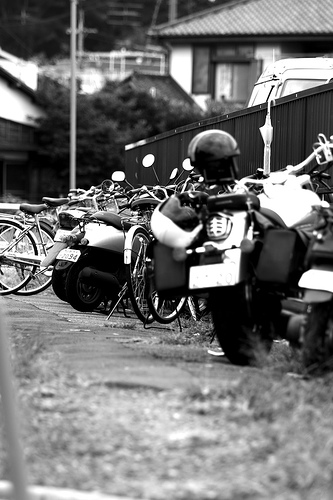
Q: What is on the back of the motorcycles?
A: Helmets.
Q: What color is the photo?
A: Black and white.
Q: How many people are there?
A: None.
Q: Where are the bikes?
A: In an urban environment.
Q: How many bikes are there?
A: About a dozen.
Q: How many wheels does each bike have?
A: Two.